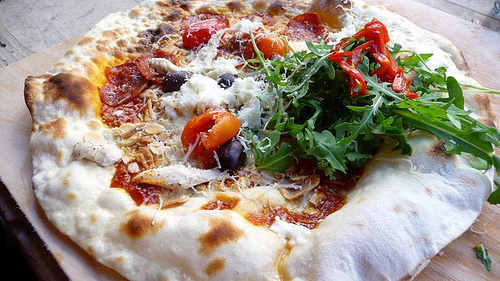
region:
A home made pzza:
[15, 10, 492, 270]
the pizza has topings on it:
[37, 37, 484, 258]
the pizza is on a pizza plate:
[103, 80, 486, 219]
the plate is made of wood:
[9, 101, 36, 215]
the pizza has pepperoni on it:
[103, 53, 143, 101]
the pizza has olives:
[221, 131, 251, 173]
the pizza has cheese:
[180, 89, 216, 101]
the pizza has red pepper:
[368, 25, 391, 65]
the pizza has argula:
[291, 81, 340, 136]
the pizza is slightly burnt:
[45, 72, 80, 94]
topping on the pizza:
[220, 135, 247, 166]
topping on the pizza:
[159, 138, 177, 154]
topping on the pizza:
[288, 172, 317, 199]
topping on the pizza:
[167, 115, 185, 127]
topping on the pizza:
[198, 45, 214, 71]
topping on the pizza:
[252, 33, 286, 58]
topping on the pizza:
[110, 74, 141, 100]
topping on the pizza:
[261, 23, 306, 50]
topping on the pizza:
[102, 65, 142, 95]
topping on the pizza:
[328, 142, 383, 172]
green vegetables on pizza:
[245, 19, 497, 217]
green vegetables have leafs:
[255, 18, 494, 212]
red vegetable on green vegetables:
[318, 3, 430, 114]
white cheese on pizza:
[152, 28, 288, 194]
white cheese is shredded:
[142, 19, 282, 194]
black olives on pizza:
[135, 45, 201, 118]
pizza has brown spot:
[112, 193, 171, 256]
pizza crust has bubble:
[7, 56, 109, 136]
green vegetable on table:
[453, 220, 498, 278]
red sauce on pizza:
[269, 172, 355, 247]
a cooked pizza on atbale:
[23, 6, 390, 275]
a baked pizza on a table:
[57, 6, 427, 280]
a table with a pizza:
[3, 13, 451, 273]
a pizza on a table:
[29, 3, 369, 271]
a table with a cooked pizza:
[0, 50, 480, 275]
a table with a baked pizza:
[47, 5, 488, 251]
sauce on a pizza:
[9, 1, 362, 278]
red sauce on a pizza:
[86, 8, 365, 215]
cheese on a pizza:
[72, 20, 416, 230]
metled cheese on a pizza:
[107, 26, 482, 262]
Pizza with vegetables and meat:
[84, 31, 409, 243]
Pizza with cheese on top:
[174, 60, 294, 130]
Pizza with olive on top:
[192, 106, 257, 176]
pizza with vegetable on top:
[286, 55, 411, 161]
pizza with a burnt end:
[22, 62, 97, 132]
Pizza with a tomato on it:
[186, 110, 227, 145]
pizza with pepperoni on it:
[100, 46, 156, 116]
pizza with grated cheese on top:
[165, 48, 303, 113]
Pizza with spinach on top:
[273, 50, 373, 155]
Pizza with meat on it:
[138, 143, 214, 216]